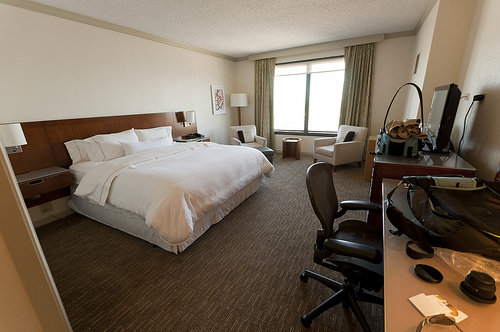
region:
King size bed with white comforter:
[65, 126, 276, 251]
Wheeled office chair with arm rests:
[301, 159, 386, 329]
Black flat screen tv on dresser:
[428, 82, 463, 157]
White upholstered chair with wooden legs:
[311, 124, 368, 166]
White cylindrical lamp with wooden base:
[229, 90, 249, 123]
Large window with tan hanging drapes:
[253, 46, 371, 133]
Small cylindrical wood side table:
[280, 133, 300, 159]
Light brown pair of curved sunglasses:
[412, 311, 467, 331]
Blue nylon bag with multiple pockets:
[379, 82, 422, 161]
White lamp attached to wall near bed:
[3, 122, 28, 157]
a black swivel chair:
[297, 158, 389, 320]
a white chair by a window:
[311, 119, 368, 171]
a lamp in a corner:
[229, 91, 250, 124]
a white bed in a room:
[65, 118, 270, 265]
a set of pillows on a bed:
[64, 123, 179, 168]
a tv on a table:
[429, 83, 461, 154]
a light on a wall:
[4, 118, 32, 155]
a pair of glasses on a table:
[407, 313, 459, 328]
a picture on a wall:
[210, 83, 228, 118]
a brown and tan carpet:
[127, 265, 268, 328]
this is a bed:
[62, 123, 275, 246]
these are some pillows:
[62, 122, 176, 171]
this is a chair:
[290, 158, 378, 326]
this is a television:
[420, 80, 463, 162]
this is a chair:
[309, 120, 369, 170]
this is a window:
[268, 55, 351, 132]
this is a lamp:
[225, 86, 250, 143]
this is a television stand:
[359, 140, 479, 235]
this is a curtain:
[251, 63, 284, 154]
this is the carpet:
[37, 143, 370, 329]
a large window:
[271, 60, 338, 130]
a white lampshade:
[228, 88, 250, 107]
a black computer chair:
[297, 160, 377, 320]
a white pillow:
[92, 124, 139, 160]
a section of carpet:
[46, 153, 368, 330]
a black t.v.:
[428, 82, 462, 157]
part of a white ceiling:
[107, 0, 435, 57]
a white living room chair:
[313, 122, 363, 162]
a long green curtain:
[253, 55, 273, 142]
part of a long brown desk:
[381, 181, 498, 330]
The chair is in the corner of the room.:
[191, 54, 298, 181]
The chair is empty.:
[220, 115, 279, 177]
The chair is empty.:
[299, 108, 376, 181]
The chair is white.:
[220, 117, 280, 176]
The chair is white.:
[306, 112, 373, 174]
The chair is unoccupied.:
[223, 112, 280, 179]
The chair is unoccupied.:
[304, 98, 374, 182]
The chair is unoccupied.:
[281, 153, 390, 328]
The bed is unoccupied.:
[52, 80, 277, 273]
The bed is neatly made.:
[51, 89, 282, 275]